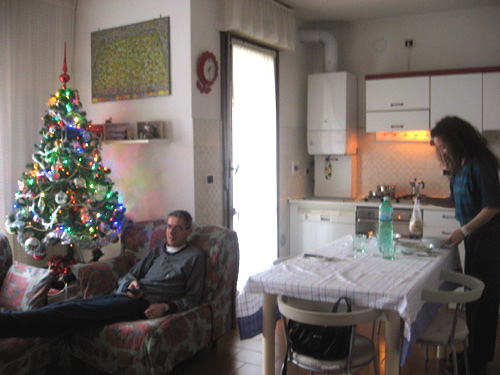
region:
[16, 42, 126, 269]
a christmas tree in the corner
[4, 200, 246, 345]
a man in a chair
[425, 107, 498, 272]
a woman standing up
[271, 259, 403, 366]
a kitchen chair at a table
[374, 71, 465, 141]
cabinets on a wall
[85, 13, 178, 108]
picture on a wall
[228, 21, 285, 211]
a door in the kitchen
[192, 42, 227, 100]
a red clock on the wall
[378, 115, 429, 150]
a light under the cabinet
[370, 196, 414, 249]
a green water bottle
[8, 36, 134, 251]
christmas tree in corner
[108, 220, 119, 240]
ornament on christmas tree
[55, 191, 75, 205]
ornament on christmas tree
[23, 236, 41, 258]
ornament on christmas tree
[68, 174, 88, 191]
ornament on christmas tree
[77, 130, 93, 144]
ornament on christmas tree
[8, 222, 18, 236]
ornament on christmas tree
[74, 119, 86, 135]
ornament on christmas tree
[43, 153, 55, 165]
ornament on christmas tree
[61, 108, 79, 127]
ornament on christmas tree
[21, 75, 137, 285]
the Christmas lights are colorful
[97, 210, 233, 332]
a man sitting on a chair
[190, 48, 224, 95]
red floral clock on a wall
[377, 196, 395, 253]
tall bottle on a table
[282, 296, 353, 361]
black bag on a chair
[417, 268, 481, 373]
chair under a table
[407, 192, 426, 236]
bag in a woman's hand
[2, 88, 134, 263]
Christmas tree with lots of lights and decorations on it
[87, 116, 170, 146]
objects on a floating shelf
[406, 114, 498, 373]
woman holding a bag over a table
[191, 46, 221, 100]
red white and black clock on a wall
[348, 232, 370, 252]
glass cup on a table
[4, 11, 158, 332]
a christmas tree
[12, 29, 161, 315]
a colorful christmas tree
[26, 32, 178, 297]
a short christmas tree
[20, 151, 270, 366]
a man sitting on a chair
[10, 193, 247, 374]
a man with his feet propped up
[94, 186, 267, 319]
a man holding a remote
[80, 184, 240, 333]
a man holding a remote control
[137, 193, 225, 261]
a man wearing glasses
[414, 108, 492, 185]
a woman with curly hair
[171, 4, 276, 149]
a clock on the wall